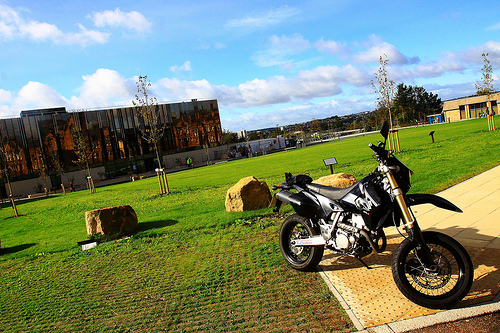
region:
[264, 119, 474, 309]
motorcycle parked on sidewalk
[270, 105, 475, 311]
parked motorcycle is black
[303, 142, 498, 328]
sidewalk is mustard yellow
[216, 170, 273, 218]
middle rock in grass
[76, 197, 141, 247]
left rock in grass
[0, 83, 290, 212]
large building behind grass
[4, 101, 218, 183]
reflection of buildings in building window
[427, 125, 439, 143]
display set in grass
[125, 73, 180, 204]
very thin tree planted in grass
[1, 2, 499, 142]
sky is partly cloudy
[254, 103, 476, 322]
the dirt bike beside the grass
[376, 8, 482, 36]
the sky is blue and clear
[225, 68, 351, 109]
the clouds in the sky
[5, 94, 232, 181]
the building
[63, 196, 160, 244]
the large rock in the grass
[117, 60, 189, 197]
the tree sapling in the grass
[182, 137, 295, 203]
the grass is trimmed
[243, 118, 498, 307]
the dirt bike is black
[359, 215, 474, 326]
the front tire of the dirt bike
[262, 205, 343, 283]
the rear tire of the dirt bike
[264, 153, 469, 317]
Black dirtbike parked on pavement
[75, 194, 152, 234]
Large rocks in grass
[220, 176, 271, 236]
Large rocks in grass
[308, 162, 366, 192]
Large rocks in grass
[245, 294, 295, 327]
Small patch of green grass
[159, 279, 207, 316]
Small patch of green grass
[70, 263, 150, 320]
Small patch of green grass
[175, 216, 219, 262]
Small patch of green grass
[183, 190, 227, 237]
Small patch of green grass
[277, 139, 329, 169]
Small patch of green grass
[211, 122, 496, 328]
The motorcycle is parked in a field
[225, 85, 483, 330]
The motorcycle was parked by its owner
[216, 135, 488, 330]
The motorcycle is parked close to a rock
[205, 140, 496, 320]
The motorcycle is parked in a city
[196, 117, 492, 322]
The motorcycle has just been purchased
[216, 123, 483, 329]
The motorcycle has a powerful motor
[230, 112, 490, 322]
The motorcycle is designed for the street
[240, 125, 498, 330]
The motorcycle is casting a shadow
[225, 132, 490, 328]
The motorcycle is painted very nicely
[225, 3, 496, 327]
The motorcycle is out in the sunshine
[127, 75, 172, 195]
A small tree.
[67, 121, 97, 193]
A small tree.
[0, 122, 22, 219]
A small tree.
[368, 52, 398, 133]
A small tree.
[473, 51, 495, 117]
A small tree.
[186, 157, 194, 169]
A person wearing green.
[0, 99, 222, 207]
A building in the background.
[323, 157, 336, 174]
A small sign in the grass.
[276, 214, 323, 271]
The rear wheel on a motorcycle.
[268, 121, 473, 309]
A black motorcycle on a ramp next to the grass.